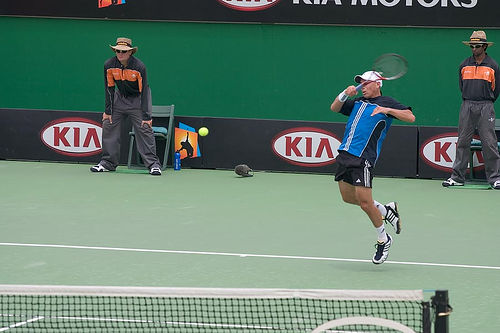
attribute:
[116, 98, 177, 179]
chair — green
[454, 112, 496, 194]
chair — green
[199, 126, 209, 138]
tennis ball — yellow green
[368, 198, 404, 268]
tennis shoes — white, black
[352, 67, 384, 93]
cap — white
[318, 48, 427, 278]
player racquet — swinging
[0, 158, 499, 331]
court — green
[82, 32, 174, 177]
man — standing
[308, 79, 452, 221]
person — wearing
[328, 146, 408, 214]
shorts — black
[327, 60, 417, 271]
man — playing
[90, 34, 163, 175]
man — leaning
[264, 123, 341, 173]
logo — kia company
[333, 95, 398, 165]
shirt — blue, dark grey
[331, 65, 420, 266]
person — male, swinging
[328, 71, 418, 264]
player — male